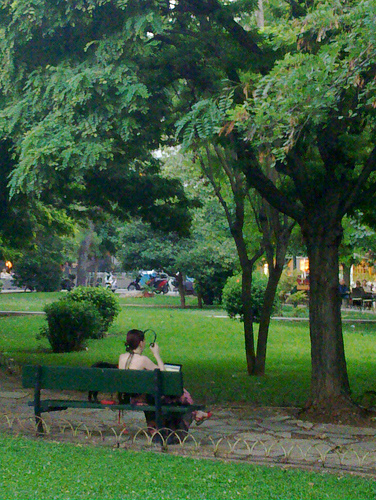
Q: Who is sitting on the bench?
A: The woman.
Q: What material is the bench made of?
A: Wood.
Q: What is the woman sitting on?
A: A bench.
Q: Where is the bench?
A: In a park.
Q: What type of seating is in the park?
A: Bench.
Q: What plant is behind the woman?
A: Grass.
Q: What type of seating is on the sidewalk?
A: A bench.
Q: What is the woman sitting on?
A: A green bench.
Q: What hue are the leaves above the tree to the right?
A: Brown and green.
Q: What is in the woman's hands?
A: Headphones.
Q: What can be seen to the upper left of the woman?
A: Leaves hanging from a branch.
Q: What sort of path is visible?
A: A stone walkway.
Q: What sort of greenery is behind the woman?
A: Grass.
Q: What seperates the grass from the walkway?
A: A wire fence.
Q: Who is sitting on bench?
A: The woman.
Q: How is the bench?
A: Green.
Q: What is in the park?
A: Trees.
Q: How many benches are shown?
A: One.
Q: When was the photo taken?
A: Daytime.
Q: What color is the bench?
A: Green.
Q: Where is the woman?
A: On the bench.